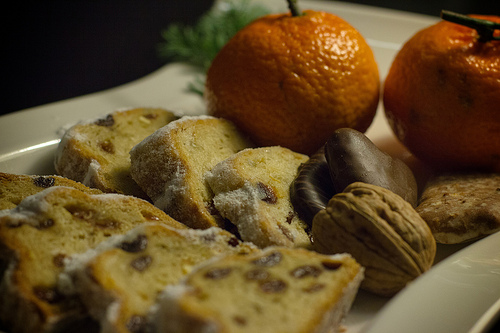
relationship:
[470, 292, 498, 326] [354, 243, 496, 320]
edge of plate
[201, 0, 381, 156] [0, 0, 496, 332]
orange on plate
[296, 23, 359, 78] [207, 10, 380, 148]
light on orange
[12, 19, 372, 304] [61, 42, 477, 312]
food on plate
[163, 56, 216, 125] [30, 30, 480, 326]
leaves on corner of plate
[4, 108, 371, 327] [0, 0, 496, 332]
bread on plate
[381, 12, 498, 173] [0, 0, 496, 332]
orange on plate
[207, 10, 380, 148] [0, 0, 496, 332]
orange on plate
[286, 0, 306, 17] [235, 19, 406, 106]
stem on orange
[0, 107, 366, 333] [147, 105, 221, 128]
bread dusted with sugar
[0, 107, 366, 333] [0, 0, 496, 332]
bread on plate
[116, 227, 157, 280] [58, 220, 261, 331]
spot on bread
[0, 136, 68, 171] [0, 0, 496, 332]
light shining on plate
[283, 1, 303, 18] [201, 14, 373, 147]
stem sticking out orange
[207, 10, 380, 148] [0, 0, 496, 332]
orange on a plate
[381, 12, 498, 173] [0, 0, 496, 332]
orange on a plate